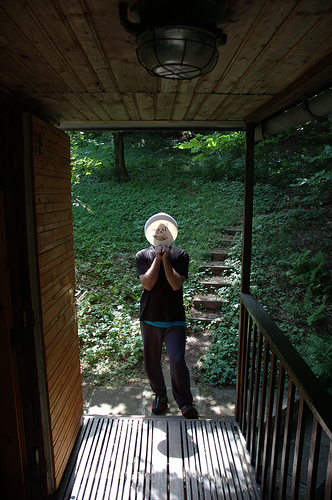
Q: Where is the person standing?
A: Edge of porch.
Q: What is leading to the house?
A: Steps.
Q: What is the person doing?
A: Holding something.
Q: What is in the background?
A: Trees.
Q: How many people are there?
A: One.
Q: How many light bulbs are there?
A: 1.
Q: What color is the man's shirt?
A: Black.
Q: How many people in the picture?
A: 1.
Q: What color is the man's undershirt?
A: Blue.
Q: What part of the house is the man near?
A: A Porch.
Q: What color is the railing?
A: Brown.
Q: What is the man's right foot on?
A: The ground.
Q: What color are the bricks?
A: Brown.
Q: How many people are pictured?
A: One.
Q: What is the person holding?
A: A frisbee.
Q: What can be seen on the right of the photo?
A: A railing.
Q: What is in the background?
A: Steps and plants.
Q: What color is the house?
A: Brown.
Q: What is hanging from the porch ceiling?
A: A light.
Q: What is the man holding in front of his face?
A: A frisbee.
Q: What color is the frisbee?
A: White.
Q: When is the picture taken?
A: Daytime.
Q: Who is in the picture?
A: A person.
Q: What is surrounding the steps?
A: Plants.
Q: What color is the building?
A: Brown.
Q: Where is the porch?
A: In front of the person.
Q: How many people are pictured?
A: 1.